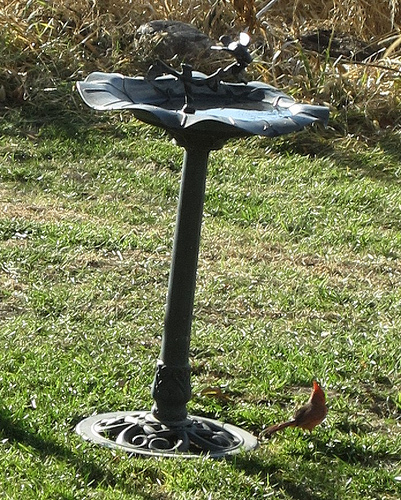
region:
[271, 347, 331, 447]
the bird is orange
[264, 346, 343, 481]
the bird on the ground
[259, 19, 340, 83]
the grass is dry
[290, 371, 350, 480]
the bird is looking up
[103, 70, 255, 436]
the fountain is green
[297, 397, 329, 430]
the wings are brown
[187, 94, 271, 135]
water in the fountain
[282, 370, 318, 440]
the bird is orange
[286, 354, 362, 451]
the bird is orange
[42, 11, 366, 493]
A bird bath in the grass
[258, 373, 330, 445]
The bird is standing on the grass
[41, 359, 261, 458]
An embellished stand for the pole of the bird bath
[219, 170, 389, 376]
The grass is yellow and green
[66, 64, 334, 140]
The pedestal has water in it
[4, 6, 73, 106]
The grass in the back is brown and dead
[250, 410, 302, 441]
The tail of the bird on the ground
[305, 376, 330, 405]
The head of the bird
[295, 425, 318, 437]
The legs of the bird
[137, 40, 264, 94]
The stand for the bird to take a bath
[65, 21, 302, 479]
a birdbath in a yard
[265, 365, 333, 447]
a cardinal next to the birdbath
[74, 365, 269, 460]
a base of a birdbath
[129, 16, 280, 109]
a sculpture in a birdbath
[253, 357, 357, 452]
the bird is red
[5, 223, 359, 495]
grass with brown spots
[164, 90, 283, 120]
water in a birdbath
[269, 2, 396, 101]
weeds behind the birdbath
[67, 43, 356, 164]
a birdbath with leaf shape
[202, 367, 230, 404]
a leaf on the ground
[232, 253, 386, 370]
the grass is very green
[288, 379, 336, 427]
the bird on the grass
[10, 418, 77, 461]
the shadow on the grass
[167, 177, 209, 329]
a black pole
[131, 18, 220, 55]
a rock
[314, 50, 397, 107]
weeds in the grass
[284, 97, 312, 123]
light on the object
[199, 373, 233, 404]
a leaf on the grass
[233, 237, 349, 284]
the grass is dry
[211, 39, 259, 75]
a statue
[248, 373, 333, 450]
bird in the grass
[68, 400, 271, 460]
base of a bird water bath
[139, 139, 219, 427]
support pole of a bird bath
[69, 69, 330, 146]
bowl of a bird bath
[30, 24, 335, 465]
metal bird bath on the grass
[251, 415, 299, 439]
tail feathers of a bird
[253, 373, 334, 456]
red and brown bird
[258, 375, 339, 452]
red and brown bird near bird bath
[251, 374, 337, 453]
red and brown bird on the grass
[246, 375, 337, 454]
red and brown bird standing